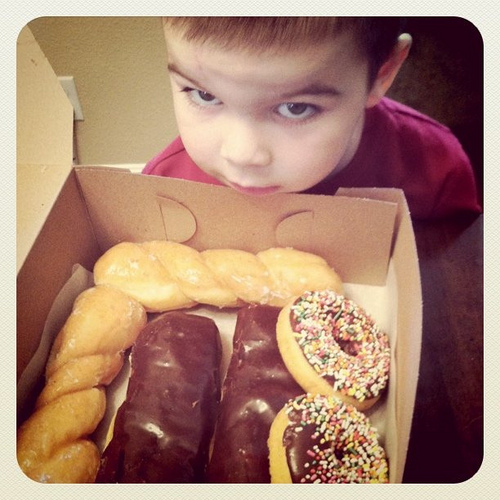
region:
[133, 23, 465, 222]
a young child's face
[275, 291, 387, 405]
a chocolate sprinkled doughnut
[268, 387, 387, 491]
a chocolate sprinkled dougnut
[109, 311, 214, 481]
a chocolate long john doughnut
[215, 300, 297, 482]
a chocolate long john doughnut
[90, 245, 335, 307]
a twist dougnut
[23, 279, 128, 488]
a twist dougnut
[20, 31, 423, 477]
a cardboard doughnut box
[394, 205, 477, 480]
a dark brown table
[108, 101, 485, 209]
a toy's red t-shirt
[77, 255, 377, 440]
donuts in the box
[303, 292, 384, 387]
sprinkles in the box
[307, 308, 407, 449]
two donuts with sprinkles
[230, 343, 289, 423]
frosting on the donut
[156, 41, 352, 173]
kid next to the donut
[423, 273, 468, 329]
table next to the box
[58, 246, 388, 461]
six donuts in box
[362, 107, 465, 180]
red shirt on kid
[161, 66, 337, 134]
eyes of the kid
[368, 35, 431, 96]
ear of the kid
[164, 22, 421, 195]
young boy's face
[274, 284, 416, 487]
donuts with sprinkles on them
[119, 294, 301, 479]
chocolate glazed donuts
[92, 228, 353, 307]
sugar glazed spiral donuts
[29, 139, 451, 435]
cardboard brown box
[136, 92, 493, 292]
little boy with red shirt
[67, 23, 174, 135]
beige painted wall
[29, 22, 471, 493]
boy holding box with pasteries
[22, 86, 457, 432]
foldable brown box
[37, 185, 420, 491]
six hole pastries on a box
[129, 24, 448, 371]
kid holding box of doughnuts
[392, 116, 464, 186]
kid wearing red shirt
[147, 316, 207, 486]
large chocolate doughnut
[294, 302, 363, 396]
chocolate doughnuts with sprinkles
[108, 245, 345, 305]
twisty glazed doughnuts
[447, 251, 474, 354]
table top is brown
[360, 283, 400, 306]
white paper in doughnut box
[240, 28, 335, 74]
kid has brown hair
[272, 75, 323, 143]
kid has gray eyes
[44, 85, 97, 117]
white electrical outlet in wall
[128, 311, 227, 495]
chocolate eclair in box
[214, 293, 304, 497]
chocolate eclair in box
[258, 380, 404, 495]
dough nut with chocolate and sprinkles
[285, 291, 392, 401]
dough nut with chocolate and sprinkles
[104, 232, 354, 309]
rope like pastry in box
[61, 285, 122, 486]
rope like pastry in box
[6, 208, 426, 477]
brown cardboard box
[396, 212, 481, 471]
brown wooden counter top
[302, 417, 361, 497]
multicolored sprinkles on frosting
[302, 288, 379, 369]
multicolored sprinkles on frosting